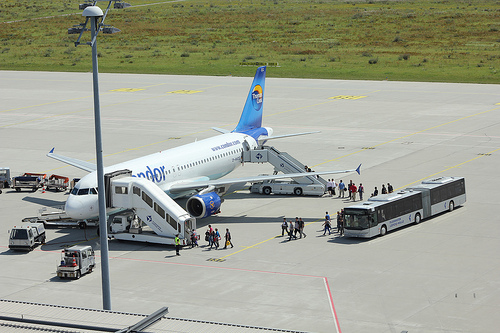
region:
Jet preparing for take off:
[46, 73, 280, 263]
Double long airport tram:
[336, 165, 467, 242]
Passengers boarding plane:
[196, 215, 333, 250]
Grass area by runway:
[129, 0, 475, 84]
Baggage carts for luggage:
[1, 161, 71, 193]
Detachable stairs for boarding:
[96, 170, 182, 242]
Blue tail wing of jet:
[206, 69, 292, 135]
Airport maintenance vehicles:
[6, 215, 90, 282]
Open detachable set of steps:
[241, 135, 335, 197]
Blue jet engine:
[180, 187, 230, 227]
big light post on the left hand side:
[72, 3, 123, 326]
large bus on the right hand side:
[303, 174, 489, 240]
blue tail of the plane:
[243, 53, 270, 142]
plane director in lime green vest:
[166, 226, 186, 258]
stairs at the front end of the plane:
[115, 172, 195, 253]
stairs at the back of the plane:
[259, 134, 349, 213]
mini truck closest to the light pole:
[52, 238, 104, 302]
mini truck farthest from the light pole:
[14, 211, 54, 269]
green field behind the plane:
[0, 2, 480, 81]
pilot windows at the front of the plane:
[67, 185, 102, 198]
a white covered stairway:
[117, 177, 203, 244]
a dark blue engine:
[181, 182, 228, 221]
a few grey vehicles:
[10, 214, 100, 290]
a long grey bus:
[319, 165, 474, 248]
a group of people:
[164, 222, 253, 257]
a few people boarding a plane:
[292, 152, 369, 203]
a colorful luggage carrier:
[8, 153, 70, 207]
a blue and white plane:
[39, 55, 368, 243]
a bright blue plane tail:
[229, 52, 274, 140]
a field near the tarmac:
[16, 35, 487, 104]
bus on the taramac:
[303, 144, 475, 267]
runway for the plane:
[303, 92, 428, 137]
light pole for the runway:
[53, 10, 130, 315]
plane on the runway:
[28, 56, 327, 281]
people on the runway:
[261, 165, 426, 212]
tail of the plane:
[206, 60, 278, 150]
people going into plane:
[143, 212, 238, 248]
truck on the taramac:
[0, 217, 54, 266]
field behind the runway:
[306, 30, 444, 67]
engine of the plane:
[184, 182, 232, 224]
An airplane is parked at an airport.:
[43, 45, 366, 252]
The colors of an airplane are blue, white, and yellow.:
[34, 24, 373, 265]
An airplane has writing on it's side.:
[102, 157, 184, 190]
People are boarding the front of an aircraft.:
[158, 200, 375, 260]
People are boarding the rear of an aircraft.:
[237, 130, 397, 206]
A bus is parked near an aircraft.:
[330, 171, 482, 245]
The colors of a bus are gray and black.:
[320, 163, 478, 253]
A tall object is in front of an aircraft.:
[67, 0, 140, 326]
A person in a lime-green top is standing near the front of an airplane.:
[171, 227, 183, 258]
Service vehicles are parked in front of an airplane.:
[5, 199, 108, 287]